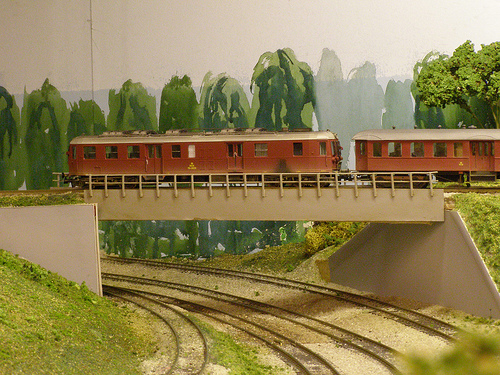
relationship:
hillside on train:
[1, 248, 138, 372] [62, 125, 500, 189]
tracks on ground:
[99, 250, 498, 374] [0, 190, 499, 374]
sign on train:
[187, 162, 197, 169] [64, 125, 499, 186]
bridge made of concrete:
[3, 165, 499, 315] [3, 170, 491, 307]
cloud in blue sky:
[1, 0, 496, 93] [0, 0, 498, 105]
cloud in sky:
[1, 0, 499, 93] [145, 30, 271, 66]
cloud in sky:
[1, 0, 496, 93] [4, 4, 498, 114]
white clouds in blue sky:
[1, 0, 498, 95] [0, 0, 498, 105]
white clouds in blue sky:
[1, 0, 499, 96] [224, 2, 451, 44]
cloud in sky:
[1, 0, 499, 93] [96, 0, 498, 33]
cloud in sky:
[1, 0, 499, 93] [330, 6, 448, 81]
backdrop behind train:
[3, 4, 495, 263] [57, 129, 499, 191]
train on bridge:
[58, 125, 498, 194] [48, 167, 452, 227]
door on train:
[139, 147, 174, 176] [49, 117, 490, 229]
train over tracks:
[62, 125, 500, 189] [64, 174, 446, 222]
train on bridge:
[62, 125, 500, 189] [38, 170, 459, 224]